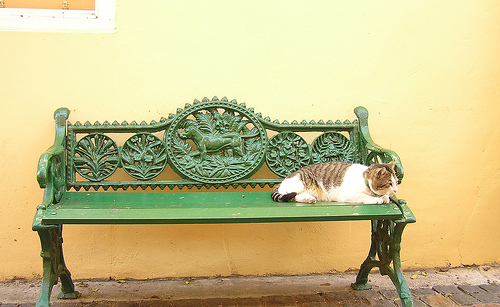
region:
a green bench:
[23, 112, 409, 297]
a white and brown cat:
[262, 158, 399, 201]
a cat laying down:
[266, 150, 396, 206]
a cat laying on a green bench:
[37, 106, 429, 297]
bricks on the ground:
[417, 286, 486, 304]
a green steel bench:
[31, 102, 420, 301]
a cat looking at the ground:
[267, 150, 407, 217]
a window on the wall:
[2, 3, 123, 37]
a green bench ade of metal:
[21, 86, 451, 296]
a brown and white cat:
[256, 139, 413, 222]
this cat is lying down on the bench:
[251, 139, 407, 212]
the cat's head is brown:
[361, 141, 402, 203]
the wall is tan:
[144, 19, 469, 91]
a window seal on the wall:
[4, 3, 136, 35]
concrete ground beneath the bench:
[66, 271, 356, 300]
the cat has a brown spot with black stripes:
[284, 148, 349, 190]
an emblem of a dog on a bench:
[170, 108, 265, 164]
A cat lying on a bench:
[276, 155, 397, 205]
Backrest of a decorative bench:
[66, 86, 352, 186]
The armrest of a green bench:
[33, 142, 68, 203]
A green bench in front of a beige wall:
[31, 93, 414, 305]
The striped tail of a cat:
[267, 186, 296, 201]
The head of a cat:
[368, 160, 398, 197]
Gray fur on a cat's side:
[321, 163, 339, 181]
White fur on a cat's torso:
[346, 171, 362, 193]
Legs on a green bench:
[18, 225, 419, 302]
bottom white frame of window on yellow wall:
[0, 1, 495, 276]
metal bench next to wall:
[30, 95, 411, 301]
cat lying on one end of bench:
[266, 155, 398, 205]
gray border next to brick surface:
[2, 265, 492, 301]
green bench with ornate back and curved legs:
[31, 95, 412, 300]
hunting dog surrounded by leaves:
[162, 95, 263, 177]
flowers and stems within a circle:
[70, 130, 115, 176]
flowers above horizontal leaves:
[120, 135, 165, 177]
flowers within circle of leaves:
[265, 126, 310, 176]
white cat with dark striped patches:
[267, 155, 399, 206]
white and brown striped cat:
[271, 161, 399, 206]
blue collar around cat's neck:
[363, 163, 385, 198]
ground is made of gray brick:
[1, 279, 497, 303]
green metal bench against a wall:
[33, 101, 415, 302]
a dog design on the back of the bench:
[163, 96, 267, 181]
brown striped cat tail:
[269, 190, 296, 203]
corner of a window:
[0, 2, 120, 36]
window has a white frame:
[0, 0, 120, 38]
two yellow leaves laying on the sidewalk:
[408, 265, 428, 280]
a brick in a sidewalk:
[458, 280, 487, 297]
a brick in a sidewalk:
[403, 282, 439, 296]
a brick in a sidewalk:
[451, 293, 478, 304]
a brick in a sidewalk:
[353, 284, 385, 299]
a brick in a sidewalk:
[366, 297, 394, 304]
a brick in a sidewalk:
[293, 290, 325, 303]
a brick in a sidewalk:
[257, 282, 287, 298]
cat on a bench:
[266, 145, 405, 212]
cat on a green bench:
[273, 147, 402, 204]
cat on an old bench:
[281, 151, 396, 208]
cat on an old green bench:
[282, 147, 394, 207]